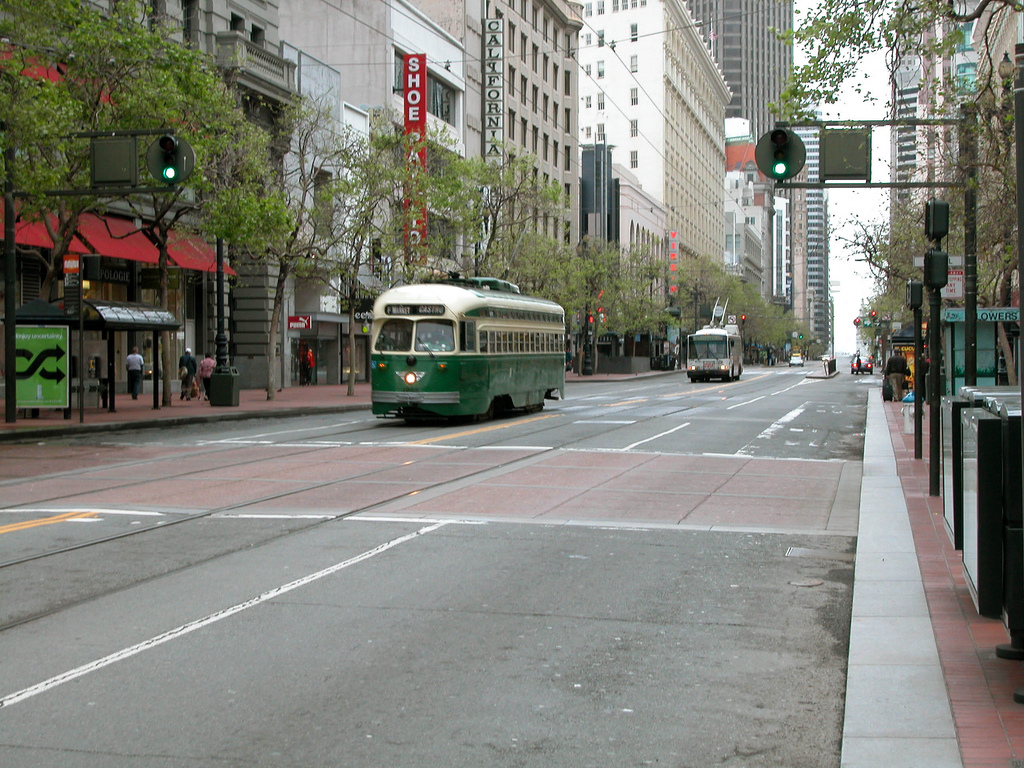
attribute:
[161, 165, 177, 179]
light — green, illuminated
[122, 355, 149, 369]
shirt — white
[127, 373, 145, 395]
pants — black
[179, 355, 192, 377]
shirt — dark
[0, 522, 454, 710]
line — white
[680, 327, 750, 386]
bus — large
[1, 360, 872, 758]
road — light grey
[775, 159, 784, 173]
street light — green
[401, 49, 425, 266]
sign — red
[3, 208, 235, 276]
awning — red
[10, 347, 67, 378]
arrow — black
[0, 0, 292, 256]
leaves — green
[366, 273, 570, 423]
bus — green and white, green and yellow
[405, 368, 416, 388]
light — white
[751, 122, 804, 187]
traffic light — green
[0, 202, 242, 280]
awning — red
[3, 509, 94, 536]
line — yellow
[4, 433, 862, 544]
crosswalk — red brick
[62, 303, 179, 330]
canopy — black